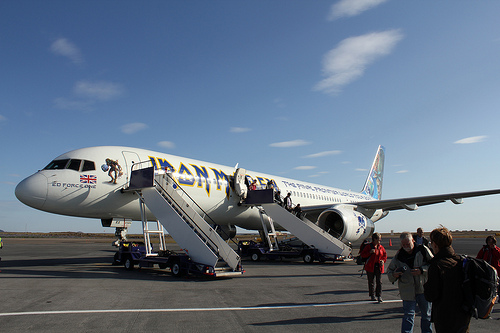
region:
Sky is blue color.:
[139, 30, 214, 95]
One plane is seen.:
[63, 142, 402, 279]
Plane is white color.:
[27, 148, 377, 260]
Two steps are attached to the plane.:
[146, 186, 339, 278]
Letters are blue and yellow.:
[146, 157, 226, 190]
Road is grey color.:
[50, 273, 105, 299]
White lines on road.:
[54, 288, 178, 325]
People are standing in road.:
[368, 233, 498, 324]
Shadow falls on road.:
[19, 241, 219, 318]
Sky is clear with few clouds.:
[25, 21, 479, 143]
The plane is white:
[11, 110, 497, 285]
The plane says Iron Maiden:
[151, 152, 283, 208]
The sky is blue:
[0, 0, 491, 260]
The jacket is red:
[355, 242, 385, 277]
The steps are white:
[125, 170, 242, 290]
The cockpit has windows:
[42, 155, 92, 175]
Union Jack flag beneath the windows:
[76, 170, 97, 185]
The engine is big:
[311, 195, 376, 261]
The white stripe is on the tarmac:
[0, 295, 407, 315]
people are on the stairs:
[246, 178, 311, 220]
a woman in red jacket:
[354, 227, 391, 305]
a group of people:
[364, 215, 492, 327]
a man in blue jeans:
[391, 230, 438, 330]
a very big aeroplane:
[10, 143, 492, 268]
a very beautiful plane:
[10, 137, 495, 247]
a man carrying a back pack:
[428, 226, 499, 330]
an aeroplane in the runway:
[11, 157, 496, 297]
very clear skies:
[31, 0, 494, 130]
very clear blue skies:
[18, 3, 299, 148]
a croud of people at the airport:
[359, 220, 495, 329]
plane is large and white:
[21, 96, 447, 286]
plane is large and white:
[27, 107, 419, 275]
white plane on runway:
[6, 145, 323, 249]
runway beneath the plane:
[1, 276, 303, 314]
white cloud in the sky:
[262, 54, 403, 126]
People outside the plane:
[346, 229, 482, 324]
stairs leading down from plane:
[146, 183, 232, 283]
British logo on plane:
[67, 163, 109, 212]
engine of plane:
[316, 197, 363, 242]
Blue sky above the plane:
[59, 56, 269, 139]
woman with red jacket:
[356, 236, 391, 295]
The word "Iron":
[149, 159, 232, 196]